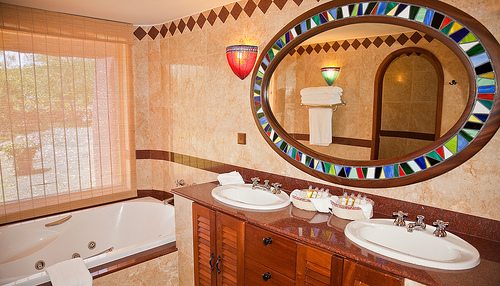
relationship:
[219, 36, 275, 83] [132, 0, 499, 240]
sconce on wall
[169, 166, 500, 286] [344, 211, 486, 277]
paneled holds sink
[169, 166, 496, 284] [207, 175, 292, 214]
paneled holds sink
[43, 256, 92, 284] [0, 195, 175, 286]
towel on bathtub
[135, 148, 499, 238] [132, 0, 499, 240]
border along wall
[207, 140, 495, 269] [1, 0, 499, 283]
sink in bathroom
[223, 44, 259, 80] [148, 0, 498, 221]
light on wall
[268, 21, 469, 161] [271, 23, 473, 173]
reflection in mirror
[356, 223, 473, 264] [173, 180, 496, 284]
sink on table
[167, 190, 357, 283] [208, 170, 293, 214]
cabinets beneath sink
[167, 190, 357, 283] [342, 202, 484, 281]
cabinets beneath sink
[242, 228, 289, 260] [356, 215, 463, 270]
drawer under sink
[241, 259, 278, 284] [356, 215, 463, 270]
drawer under sink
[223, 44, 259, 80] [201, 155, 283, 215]
light next to sink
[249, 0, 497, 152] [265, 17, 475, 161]
pattern adorning mirror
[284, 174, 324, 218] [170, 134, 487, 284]
basket between sinks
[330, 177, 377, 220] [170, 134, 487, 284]
basket between sinks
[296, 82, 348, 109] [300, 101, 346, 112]
towels on holders